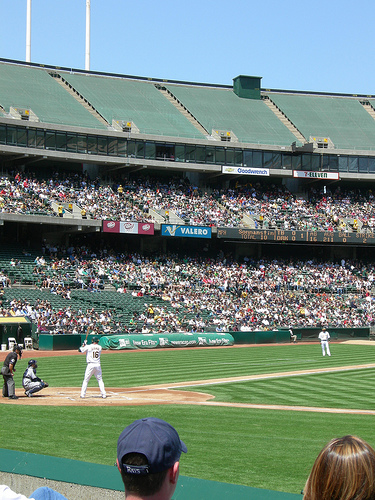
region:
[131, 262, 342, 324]
Hundreds of people in the stand.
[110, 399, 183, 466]
Person wearing a blue cap.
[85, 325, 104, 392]
Player holding a bat.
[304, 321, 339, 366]
Player in the field.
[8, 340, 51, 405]
Umpire is behind the catcher.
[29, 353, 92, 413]
The catcher is behind home plate.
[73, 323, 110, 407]
The player is on the side of home plate.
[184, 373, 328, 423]
White lines in the field.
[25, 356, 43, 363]
The player is wearing a blue helmet.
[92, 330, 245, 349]
Advertisement of the green wall.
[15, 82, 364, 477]
A large baseball stadium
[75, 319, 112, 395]
A baseball batter with bat in the air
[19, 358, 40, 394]
Catcher squatting behind batter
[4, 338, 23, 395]
Umpire standing behind catcher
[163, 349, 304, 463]
A large green baseball field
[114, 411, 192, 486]
A dark blue cap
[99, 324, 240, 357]
A long green sign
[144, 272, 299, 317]
A large crowd of people in the stadium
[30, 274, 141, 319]
A large area of green stadium seat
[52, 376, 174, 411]
Home plate with white chalk markings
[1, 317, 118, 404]
players on a baseball field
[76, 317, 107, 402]
a man holding a bat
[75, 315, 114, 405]
a baseball player holding a bat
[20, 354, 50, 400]
a catcher on the field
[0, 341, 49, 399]
an umpire behind the catcher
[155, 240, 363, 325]
spectators at a baseball game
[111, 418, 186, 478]
a man wearing a blue hat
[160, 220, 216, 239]
a sign that says Valero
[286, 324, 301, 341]
a man sitting in a chair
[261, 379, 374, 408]
mowing pattern in the grass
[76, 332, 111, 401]
battter waiting for pitch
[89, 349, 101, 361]
number 16 on jersey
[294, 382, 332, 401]
freshly cut green grass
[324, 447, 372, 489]
woman's brown streaked hair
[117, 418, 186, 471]
man's navy blue hat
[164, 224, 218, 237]
valero gas advertisement in stadium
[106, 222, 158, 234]
dr pepper banner ad in stadium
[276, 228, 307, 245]
baseball game's score board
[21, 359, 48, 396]
catcher for the pitching team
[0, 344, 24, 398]
umpire for the baseball game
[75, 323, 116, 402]
Baseball player ready to bat.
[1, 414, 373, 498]
Spectators in the foreground.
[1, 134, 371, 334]
Spectators in the background.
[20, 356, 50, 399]
Catcher ready for the pitch.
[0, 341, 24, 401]
Umpire ready for the play.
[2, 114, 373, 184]
Skybox seats up high.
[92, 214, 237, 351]
Advertising on signs around the stadium.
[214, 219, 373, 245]
The score being shown up high.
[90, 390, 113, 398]
Home plate on the field.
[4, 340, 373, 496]
Green striped field where players are playing.